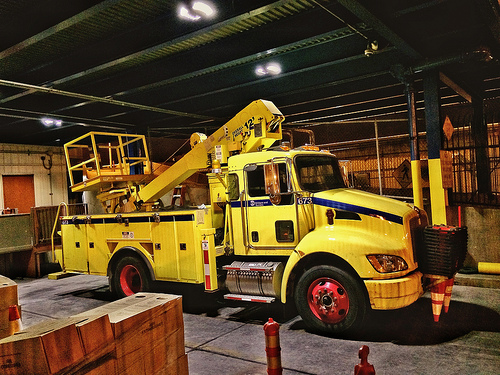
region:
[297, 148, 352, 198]
window of the truck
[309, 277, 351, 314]
red rim of tire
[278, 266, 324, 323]
black tire on ground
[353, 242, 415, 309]
light on front of truck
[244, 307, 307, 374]
red and silver item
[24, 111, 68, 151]
light on top of roof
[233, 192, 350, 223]
blue strip of truck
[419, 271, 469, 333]
orange and white cone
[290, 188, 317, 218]
number on side of truck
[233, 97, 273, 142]
the number twelve on truck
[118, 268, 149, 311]
the truck rim is red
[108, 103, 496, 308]
the utility truck is yellow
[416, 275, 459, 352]
hazard cones on the front of te truck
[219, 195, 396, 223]
blue stripe on the truck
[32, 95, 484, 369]
utility truck parked inside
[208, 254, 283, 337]
two sets of steps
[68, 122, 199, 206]
bucket on the back of truck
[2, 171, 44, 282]
door in the building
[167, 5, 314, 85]
lights in the ceiling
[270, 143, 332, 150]
yellow lights on top of truck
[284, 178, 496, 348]
red wheel on truck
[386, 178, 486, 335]
orange and white cones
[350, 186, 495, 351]
cones stacked on truck front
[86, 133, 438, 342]
yellow truck with blue stripe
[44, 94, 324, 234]
lift on back of truck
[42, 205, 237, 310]
compartments on side of truck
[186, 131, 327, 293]
passenger door of truck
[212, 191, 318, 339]
metal steps on truck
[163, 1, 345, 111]
overhead lights are on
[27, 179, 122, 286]
step and rail on back of truck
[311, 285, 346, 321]
a red wheel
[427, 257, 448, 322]
orange and white cones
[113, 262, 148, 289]
the back tire of the truck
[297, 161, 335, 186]
the windshield of the truck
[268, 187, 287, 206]
side mirror of the truck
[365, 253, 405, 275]
the headlights on the truck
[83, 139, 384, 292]
a yellow truck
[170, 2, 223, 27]
lights up above on the ceiling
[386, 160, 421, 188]
a yellow traffic sign in the background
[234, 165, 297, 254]
it is the door on the truck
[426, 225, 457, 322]
Two stacks of upside down orange cones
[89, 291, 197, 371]
Stack of crates in a warehouse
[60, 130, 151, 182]
Yellow cage on the back of a truck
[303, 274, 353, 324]
Red hub cab on a black wheel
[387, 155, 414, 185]
Yellow crossing sign in a warehouse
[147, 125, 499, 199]
Fence behind a truck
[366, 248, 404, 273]
Headlight on front of a truck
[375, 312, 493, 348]
Shadow of a truck on the ground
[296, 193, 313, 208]
White numbers 673 on a truck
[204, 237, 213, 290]
Red and white reflectors on a truck